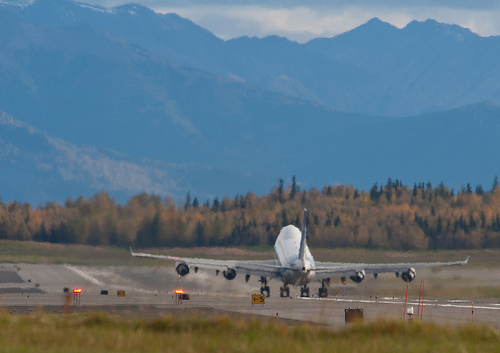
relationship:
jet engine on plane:
[352, 267, 365, 279] [122, 226, 470, 298]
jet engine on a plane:
[273, 224, 315, 296] [97, 198, 447, 319]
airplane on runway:
[127, 205, 476, 300] [33, 249, 498, 328]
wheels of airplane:
[257, 280, 342, 301] [132, 213, 480, 288]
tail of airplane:
[258, 207, 340, 272] [127, 205, 476, 300]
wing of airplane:
[311, 253, 472, 283] [127, 205, 476, 300]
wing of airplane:
[126, 242, 279, 280] [127, 205, 476, 300]